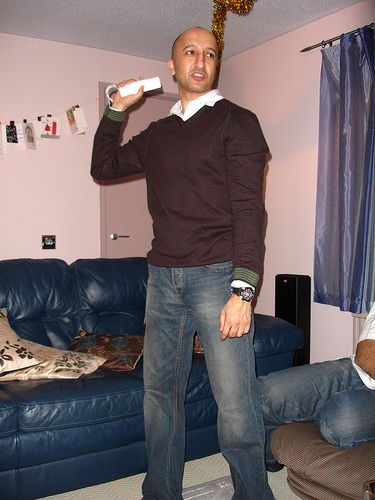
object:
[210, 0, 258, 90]
christmas tinsel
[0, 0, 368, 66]
ceiling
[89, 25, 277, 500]
man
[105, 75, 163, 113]
wii controller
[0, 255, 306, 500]
couch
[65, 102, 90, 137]
christmas cards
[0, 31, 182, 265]
wall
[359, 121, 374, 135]
curtains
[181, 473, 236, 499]
rug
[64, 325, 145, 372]
pillow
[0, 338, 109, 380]
pillow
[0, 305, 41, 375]
pillow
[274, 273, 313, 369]
speaker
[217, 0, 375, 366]
wall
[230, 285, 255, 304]
watch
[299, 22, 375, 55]
rod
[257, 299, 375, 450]
person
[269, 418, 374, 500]
chair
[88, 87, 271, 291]
shirt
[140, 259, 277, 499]
jeans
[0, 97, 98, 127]
string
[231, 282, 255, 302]
wrist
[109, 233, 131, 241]
handle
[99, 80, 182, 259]
door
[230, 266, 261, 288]
cuff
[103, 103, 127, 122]
cuff